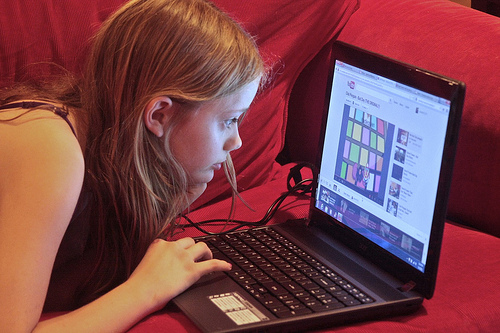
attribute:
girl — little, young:
[1, 1, 263, 332]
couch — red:
[1, 0, 500, 331]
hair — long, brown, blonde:
[8, 0, 265, 314]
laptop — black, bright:
[171, 40, 465, 332]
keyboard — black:
[189, 226, 377, 319]